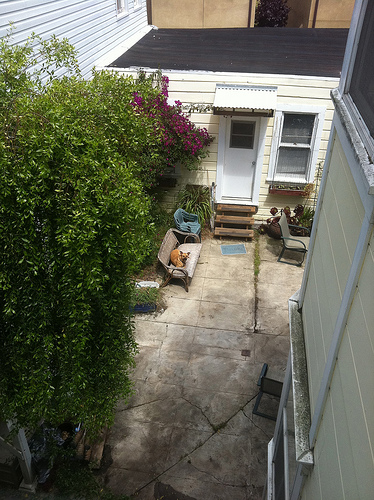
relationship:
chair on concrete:
[276, 213, 310, 266] [95, 234, 306, 497]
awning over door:
[211, 81, 279, 112] [213, 116, 267, 207]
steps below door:
[211, 198, 259, 248] [223, 118, 263, 200]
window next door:
[267, 105, 322, 189] [211, 111, 264, 202]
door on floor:
[219, 240, 247, 256] [0, 234, 316, 499]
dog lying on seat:
[173, 248, 191, 270] [168, 240, 204, 282]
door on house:
[204, 114, 261, 208] [193, 67, 301, 217]